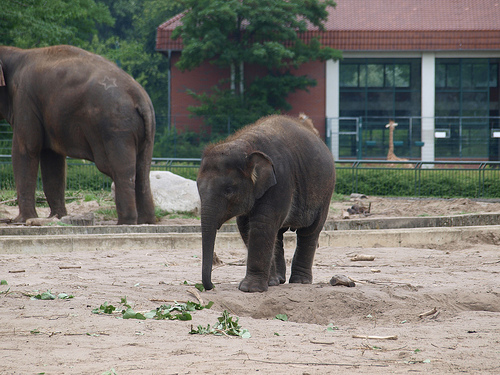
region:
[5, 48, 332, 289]
two elephants at the zoo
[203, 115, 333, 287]
a baby elephant calf in the dirt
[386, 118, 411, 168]
a giraffe in the background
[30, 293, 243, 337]
green leaves on the ground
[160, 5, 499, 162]
a big red building with large glass windows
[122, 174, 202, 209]
a big boulder behind the elephants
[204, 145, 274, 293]
the baby elephant's head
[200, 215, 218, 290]
the baby elephant's trunk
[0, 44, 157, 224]
the large elephant on the left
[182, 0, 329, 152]
trees in front of the building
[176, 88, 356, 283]
the elephant on the sand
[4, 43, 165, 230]
the large elephant on the sand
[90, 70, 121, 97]
the star on the elephant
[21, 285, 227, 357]
the leaves on the sand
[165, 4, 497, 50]
the roof of the building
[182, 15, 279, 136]
the large tree beside the building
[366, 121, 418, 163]
the giraffe in the background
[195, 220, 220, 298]
the trunk of the elephant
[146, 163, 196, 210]
the rock beside the elephant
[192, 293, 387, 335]
the hole in the sand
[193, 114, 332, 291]
a small Indian elephant walking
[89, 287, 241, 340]
tree leaves recently placed on the ground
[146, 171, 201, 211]
a white boulder beyond the larger elephant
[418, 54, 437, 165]
a column on the building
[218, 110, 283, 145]
wiry hair on the elephant's back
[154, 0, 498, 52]
the roof of the building in the distance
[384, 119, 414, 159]
a giraffe close to the building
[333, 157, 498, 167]
a metal bar that tops a barrier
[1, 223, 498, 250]
a curb in the elephant pen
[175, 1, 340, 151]
two trees growing close to each other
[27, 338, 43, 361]
Patch of brown dirt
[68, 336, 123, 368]
Patch of brown dirt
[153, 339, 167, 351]
Patch of brown dirt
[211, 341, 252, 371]
Patch of brown dirt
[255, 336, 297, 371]
Patch of brown dirt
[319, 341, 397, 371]
Patch of brown dirt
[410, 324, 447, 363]
Patch of brown dirt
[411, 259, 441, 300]
Patch of brown dirt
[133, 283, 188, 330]
Patch of brown dirt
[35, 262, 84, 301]
Patch of brown dirt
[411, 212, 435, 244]
part of a pavement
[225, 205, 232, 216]
part of a trunk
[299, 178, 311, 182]
side of an elephant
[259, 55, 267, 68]
part of a tree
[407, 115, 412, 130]
part of a window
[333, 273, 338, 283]
part of a rock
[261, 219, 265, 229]
edge of a leg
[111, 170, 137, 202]
back of a leg